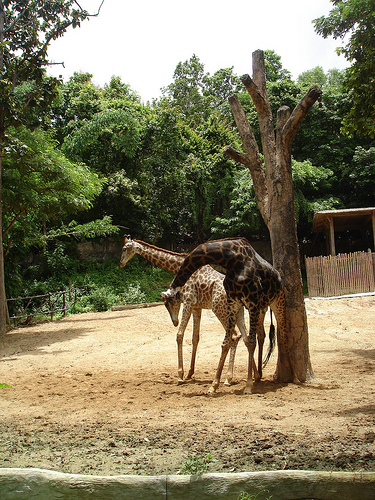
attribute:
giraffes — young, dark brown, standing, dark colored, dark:
[159, 236, 303, 387]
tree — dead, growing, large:
[220, 49, 328, 389]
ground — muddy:
[2, 295, 374, 472]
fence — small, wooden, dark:
[305, 249, 374, 300]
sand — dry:
[4, 299, 375, 365]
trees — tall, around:
[313, 0, 373, 147]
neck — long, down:
[138, 242, 187, 276]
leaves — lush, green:
[340, 130, 346, 138]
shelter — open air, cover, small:
[310, 205, 374, 254]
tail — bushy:
[264, 308, 277, 372]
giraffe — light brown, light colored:
[116, 236, 261, 387]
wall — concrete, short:
[1, 467, 374, 500]